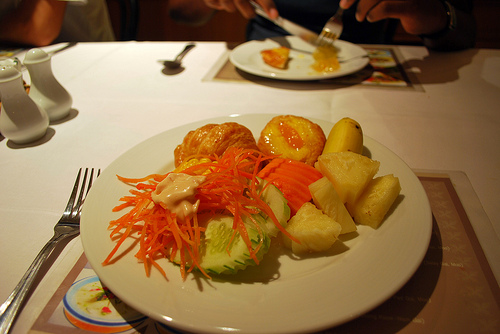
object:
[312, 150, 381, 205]
meal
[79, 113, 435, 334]
plate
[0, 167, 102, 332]
fork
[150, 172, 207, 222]
dressing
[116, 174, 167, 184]
carrots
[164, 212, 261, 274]
cucumber slices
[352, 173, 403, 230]
pineapple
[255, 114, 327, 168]
scallop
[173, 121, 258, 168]
croissant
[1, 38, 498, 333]
table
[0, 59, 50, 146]
salt shaker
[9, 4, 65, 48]
elbow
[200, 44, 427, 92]
paper place mat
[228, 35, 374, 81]
plate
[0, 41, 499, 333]
tablecloth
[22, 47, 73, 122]
salt shaker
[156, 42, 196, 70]
spoon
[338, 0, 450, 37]
hand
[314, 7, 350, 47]
fork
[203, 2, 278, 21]
hand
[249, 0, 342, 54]
knife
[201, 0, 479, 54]
man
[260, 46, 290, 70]
food